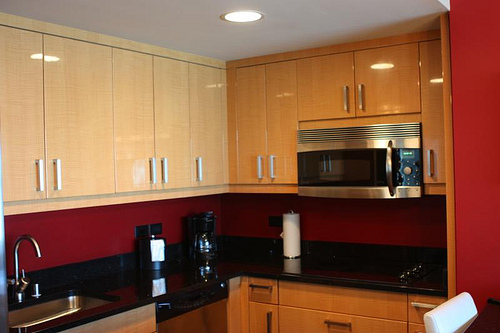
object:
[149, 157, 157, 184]
handle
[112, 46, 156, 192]
cabinet door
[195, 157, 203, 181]
handle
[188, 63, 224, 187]
cabinet door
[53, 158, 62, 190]
handle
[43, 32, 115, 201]
cabinet door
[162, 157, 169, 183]
handle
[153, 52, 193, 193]
cabinet door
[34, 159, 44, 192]
handle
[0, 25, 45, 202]
cabinet door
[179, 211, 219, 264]
coffee maker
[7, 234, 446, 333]
counter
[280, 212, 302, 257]
paper towels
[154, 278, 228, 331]
dishwasher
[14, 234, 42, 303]
faucet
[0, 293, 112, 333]
sink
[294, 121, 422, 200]
microwave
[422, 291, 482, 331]
chair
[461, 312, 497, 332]
table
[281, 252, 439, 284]
stove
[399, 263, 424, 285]
knobs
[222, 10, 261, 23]
recessed light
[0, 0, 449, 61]
ceiling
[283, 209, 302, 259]
towel holder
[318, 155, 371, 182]
window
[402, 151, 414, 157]
digital display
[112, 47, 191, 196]
cabinet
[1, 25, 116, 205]
cabinet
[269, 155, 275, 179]
handles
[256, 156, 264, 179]
handles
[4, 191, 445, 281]
wall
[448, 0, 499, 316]
wall